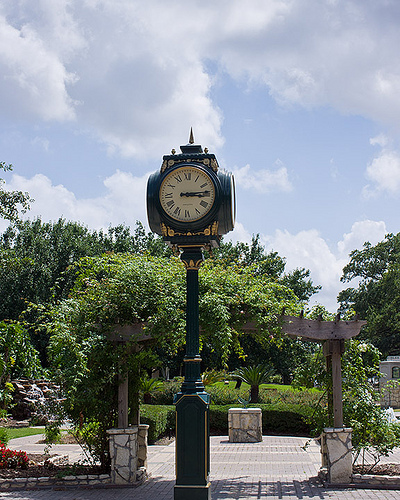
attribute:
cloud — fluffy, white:
[85, 36, 190, 121]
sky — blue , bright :
[2, 0, 398, 322]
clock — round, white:
[158, 165, 214, 235]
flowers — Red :
[1, 443, 31, 475]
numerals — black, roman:
[164, 172, 212, 217]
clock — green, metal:
[157, 164, 215, 223]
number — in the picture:
[199, 199, 209, 207]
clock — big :
[159, 164, 222, 226]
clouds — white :
[51, 22, 215, 139]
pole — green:
[171, 249, 214, 499]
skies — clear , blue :
[1, 1, 398, 312]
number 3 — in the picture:
[200, 189, 212, 199]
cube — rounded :
[143, 118, 245, 262]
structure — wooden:
[271, 302, 375, 441]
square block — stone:
[224, 403, 266, 444]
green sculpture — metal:
[232, 387, 257, 408]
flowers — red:
[1, 442, 46, 482]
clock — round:
[155, 145, 224, 241]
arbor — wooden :
[97, 301, 370, 490]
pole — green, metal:
[175, 250, 215, 498]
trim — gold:
[179, 253, 212, 489]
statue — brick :
[237, 396, 255, 408]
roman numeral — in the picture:
[193, 170, 202, 184]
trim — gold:
[174, 213, 190, 233]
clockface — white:
[151, 159, 223, 231]